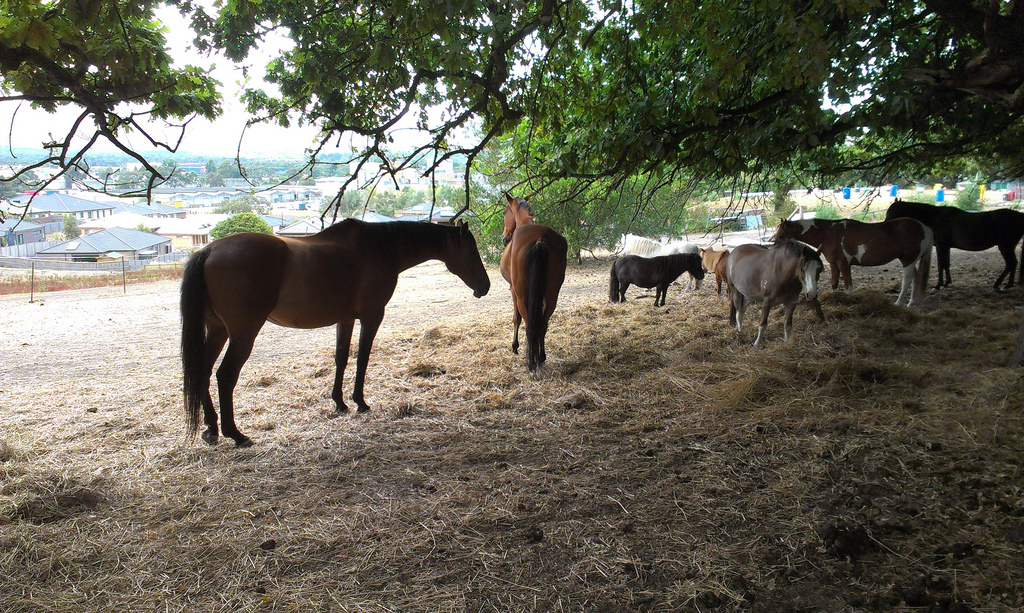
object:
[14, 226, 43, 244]
wall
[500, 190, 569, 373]
horses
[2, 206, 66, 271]
building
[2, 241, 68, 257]
wall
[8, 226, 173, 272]
building